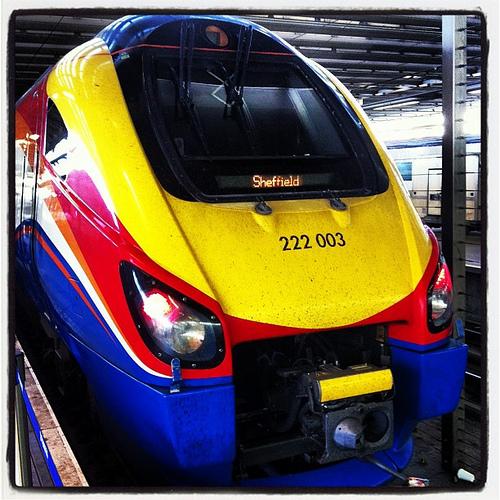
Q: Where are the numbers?
A: Front of vehicle.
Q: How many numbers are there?
A: Six.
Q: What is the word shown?
A: Sheffield.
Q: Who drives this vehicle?
A: A conductor.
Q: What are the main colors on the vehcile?
A: Yellow, red, blue.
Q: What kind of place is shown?
A: Station.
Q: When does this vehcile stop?
A: When destination is reached.